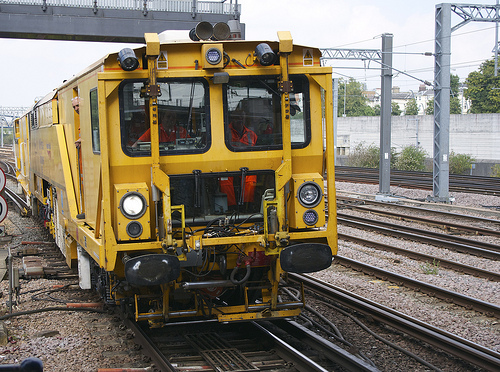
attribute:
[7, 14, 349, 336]
train — yellow, brown 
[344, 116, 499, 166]
wall — made of bricks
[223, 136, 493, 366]
track — train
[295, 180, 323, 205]
light — out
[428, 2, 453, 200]
post — tall, gray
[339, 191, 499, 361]
tracks — several sets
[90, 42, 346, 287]
train — short, yellow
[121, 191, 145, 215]
light — on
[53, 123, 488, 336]
tracks — several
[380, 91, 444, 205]
poles — large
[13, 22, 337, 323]
train — near land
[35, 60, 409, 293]
train — yellow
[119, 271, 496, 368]
tracks — steel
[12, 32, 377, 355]
train — yellow